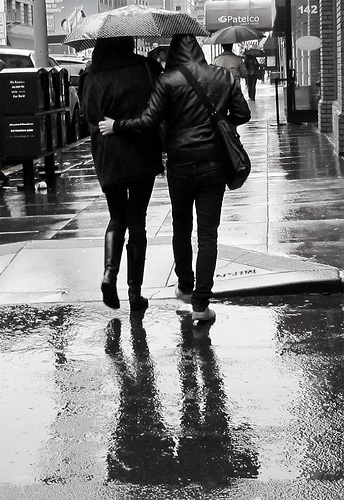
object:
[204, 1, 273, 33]
awning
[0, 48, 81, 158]
cars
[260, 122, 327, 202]
street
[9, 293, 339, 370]
street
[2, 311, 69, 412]
puddle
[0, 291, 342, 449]
street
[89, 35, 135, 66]
head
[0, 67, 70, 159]
boxes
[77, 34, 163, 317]
person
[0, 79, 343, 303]
sidewalk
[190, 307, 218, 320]
shoe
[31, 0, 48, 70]
pole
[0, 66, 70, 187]
dispenser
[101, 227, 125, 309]
boot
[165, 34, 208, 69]
head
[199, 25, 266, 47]
plain umbrella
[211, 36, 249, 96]
man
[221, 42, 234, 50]
head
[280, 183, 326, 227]
road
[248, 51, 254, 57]
head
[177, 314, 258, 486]
shadows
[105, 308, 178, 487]
shadows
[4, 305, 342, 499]
road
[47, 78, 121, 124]
wall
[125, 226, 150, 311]
boot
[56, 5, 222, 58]
umbrella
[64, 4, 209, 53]
umbrella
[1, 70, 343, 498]
wet paved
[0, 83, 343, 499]
sidewalk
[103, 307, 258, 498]
reflection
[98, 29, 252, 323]
pedestrians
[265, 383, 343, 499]
street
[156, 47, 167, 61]
heads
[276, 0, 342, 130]
building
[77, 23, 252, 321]
couple